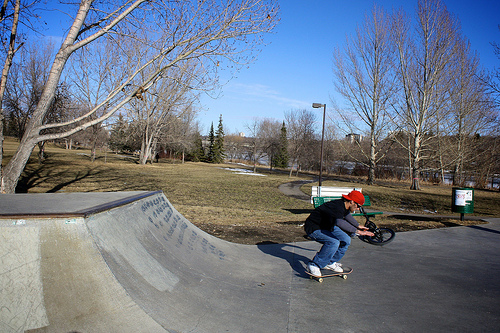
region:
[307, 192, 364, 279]
Man skating on concrete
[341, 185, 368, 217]
Man wearing red hat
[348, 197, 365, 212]
Man wearing dark sunglasses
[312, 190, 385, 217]
Green and black bench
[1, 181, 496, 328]
Grey colored skating ramp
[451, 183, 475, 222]
Green colored trash can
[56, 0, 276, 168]
Bare trees in park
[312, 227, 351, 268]
Man wearing blue jeans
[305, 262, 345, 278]
Man wearing white shoes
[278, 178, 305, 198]
Grey colored walking path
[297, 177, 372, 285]
a man on a skateboard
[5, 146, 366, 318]
a ramp used for skateboards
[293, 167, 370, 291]
a man wearing a red cap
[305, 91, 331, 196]
a light along a path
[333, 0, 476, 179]
a group of trees with no leafs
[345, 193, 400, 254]
a bike laying next to a bench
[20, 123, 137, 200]
shadow of a large tree on the ground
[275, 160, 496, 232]
a bike path threw the park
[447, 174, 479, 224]
a green garbage can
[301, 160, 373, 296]
a man trying to keep his balance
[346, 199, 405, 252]
a bicycle laying next to a bench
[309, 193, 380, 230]
a green bench at a skate park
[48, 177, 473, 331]
a ramp at a skatepark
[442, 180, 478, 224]
a green trash bin at a skate park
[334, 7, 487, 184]
three bare trees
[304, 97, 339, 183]
a tall light post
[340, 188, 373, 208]
a red hat on a man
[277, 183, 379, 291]
a skateboard on a ramp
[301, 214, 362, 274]
blue jeans on a man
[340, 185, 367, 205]
a red baseball cap on the man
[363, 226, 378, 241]
the hand of a man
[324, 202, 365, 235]
the arm of a man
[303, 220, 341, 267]
the leg of a man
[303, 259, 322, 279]
a white shoe on the man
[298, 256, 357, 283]
a black skateboard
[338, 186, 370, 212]
the head of the man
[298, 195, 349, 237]
a black tee shirt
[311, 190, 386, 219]
a green park bench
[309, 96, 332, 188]
a black light pole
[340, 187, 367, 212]
man wearing red cap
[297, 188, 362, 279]
man ducking on skateboard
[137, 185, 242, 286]
concrete ramp with black characters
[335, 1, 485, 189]
three trees with no leaves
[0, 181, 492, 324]
skateboard ramp in a park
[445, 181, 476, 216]
green trash can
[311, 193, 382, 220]
green park bench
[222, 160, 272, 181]
patch of white snow in a park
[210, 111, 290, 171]
tall coniferous trees in a park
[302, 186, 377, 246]
man wearing black shirt